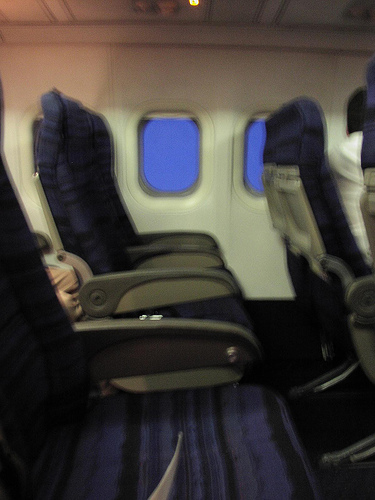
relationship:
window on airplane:
[138, 111, 203, 196] [0, 0, 373, 499]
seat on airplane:
[26, 87, 255, 329] [0, 0, 373, 499]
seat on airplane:
[0, 149, 321, 500] [0, 0, 373, 499]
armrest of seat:
[80, 262, 242, 320] [26, 87, 255, 329]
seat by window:
[26, 87, 255, 329] [138, 111, 203, 196]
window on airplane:
[240, 116, 272, 196] [0, 0, 373, 499]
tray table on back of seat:
[273, 167, 330, 279] [273, 95, 370, 386]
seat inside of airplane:
[26, 87, 255, 329] [0, 0, 373, 499]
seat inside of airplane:
[0, 149, 321, 500] [0, 0, 373, 499]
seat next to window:
[26, 87, 255, 329] [138, 111, 203, 196]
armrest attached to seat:
[80, 262, 242, 320] [26, 87, 255, 329]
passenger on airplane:
[326, 86, 374, 268] [0, 0, 373, 499]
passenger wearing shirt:
[326, 86, 374, 268] [328, 131, 371, 269]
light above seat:
[187, 0, 201, 8] [26, 87, 255, 329]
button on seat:
[223, 346, 241, 367] [0, 149, 321, 500]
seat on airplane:
[273, 95, 370, 386] [0, 0, 373, 499]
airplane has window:
[0, 0, 373, 499] [138, 111, 203, 196]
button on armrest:
[223, 346, 241, 367] [70, 320, 264, 382]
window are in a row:
[240, 116, 272, 196] [34, 157, 351, 195]